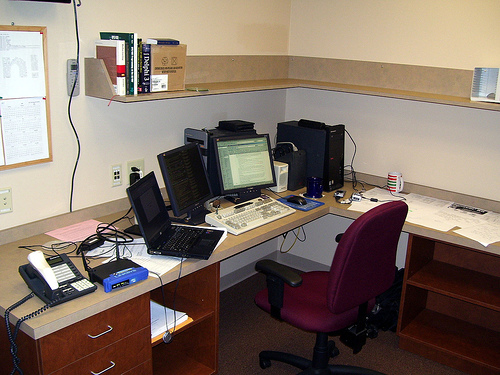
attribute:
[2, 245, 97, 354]
telephone — black, white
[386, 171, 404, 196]
cup — green, red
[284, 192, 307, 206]
mouse — black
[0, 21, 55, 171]
board — bulletin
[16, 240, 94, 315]
telephone — black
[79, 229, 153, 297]
computer router — black, blue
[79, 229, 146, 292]
router — black, blue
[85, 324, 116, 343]
handle — metal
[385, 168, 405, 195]
mug — red, green, striped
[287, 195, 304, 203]
computer mouse — black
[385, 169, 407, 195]
mug — colorful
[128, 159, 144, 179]
outlet — white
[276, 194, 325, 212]
mousepad — blue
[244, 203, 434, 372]
chair — purple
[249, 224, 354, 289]
arms — black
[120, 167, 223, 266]
laptop — black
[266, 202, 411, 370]
chair — maroon, desk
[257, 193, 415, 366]
chair — red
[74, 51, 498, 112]
shelf — corner